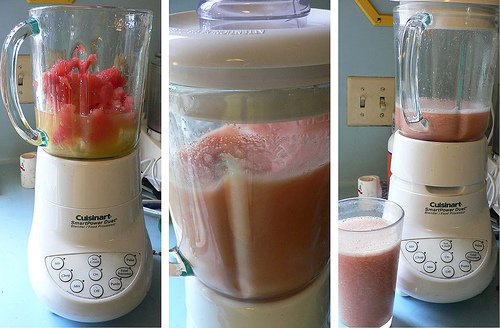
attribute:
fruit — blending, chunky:
[35, 45, 141, 157]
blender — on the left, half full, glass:
[0, 2, 162, 328]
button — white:
[85, 251, 103, 269]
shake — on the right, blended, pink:
[337, 215, 404, 327]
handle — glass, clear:
[0, 15, 54, 155]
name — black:
[65, 209, 123, 234]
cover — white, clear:
[164, 0, 332, 87]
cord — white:
[138, 153, 168, 216]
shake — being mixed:
[391, 96, 490, 141]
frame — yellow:
[353, 1, 393, 29]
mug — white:
[357, 174, 385, 201]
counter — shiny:
[0, 155, 159, 327]